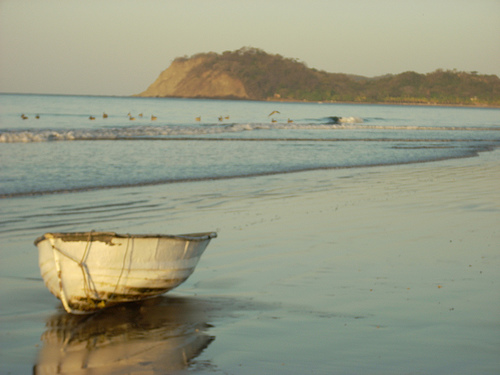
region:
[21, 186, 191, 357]
Boat on the shore.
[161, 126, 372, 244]
Water touching the shore.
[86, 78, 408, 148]
Birds in the water.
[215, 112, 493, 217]
Water in the background.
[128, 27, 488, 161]
Hills behind the water.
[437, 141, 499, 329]
Sand on the shore.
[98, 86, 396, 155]
Rocks in the water.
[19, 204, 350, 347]
White boat on the shore.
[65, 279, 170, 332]
Dirt on the boat.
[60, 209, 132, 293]
Ropes on the boat.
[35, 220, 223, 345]
white boat on wet sand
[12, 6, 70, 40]
white clouds against blue sky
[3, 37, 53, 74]
white clouds against blue sky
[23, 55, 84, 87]
white clouds against blue sky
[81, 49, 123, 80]
white clouds against blue sky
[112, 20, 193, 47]
white clouds against blue sky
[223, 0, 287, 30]
white clouds against blue sky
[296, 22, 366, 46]
white clouds against blue sky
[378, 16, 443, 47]
white clouds against blue sky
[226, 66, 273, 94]
brown mountain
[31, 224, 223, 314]
The boat is old.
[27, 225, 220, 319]
The boat is white.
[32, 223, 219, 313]
The boat is on it's keel.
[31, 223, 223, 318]
The boat is on the beach.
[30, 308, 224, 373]
The boat is reflected in the water.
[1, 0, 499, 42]
The sky is gray and cloudy.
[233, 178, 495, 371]
The beach is wet.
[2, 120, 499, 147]
A wave is coming towards the beach.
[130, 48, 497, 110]
The coast has green in it.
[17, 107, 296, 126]
Birds are moving in the water.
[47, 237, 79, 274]
a white boat on the shore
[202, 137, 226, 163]
the blue ocean in the background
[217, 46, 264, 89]
the mountains in the background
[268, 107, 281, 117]
a white seagull flying by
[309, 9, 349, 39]
the clear blue sky in the background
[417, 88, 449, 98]
the lush green trees in the distance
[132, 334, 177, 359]
the shadow of the boat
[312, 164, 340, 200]
ripples on the shore line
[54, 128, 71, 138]
the waves crashing on the shore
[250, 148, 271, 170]
the blue clear ocean waves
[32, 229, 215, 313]
White boat on shore.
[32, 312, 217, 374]
Shadow of a white boat on the shore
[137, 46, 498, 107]
Large land mass in the distance.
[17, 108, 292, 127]
Many birds over the water.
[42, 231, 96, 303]
Rope on the side of the boat in the shape of a Y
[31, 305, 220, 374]
White boat reflection on the sand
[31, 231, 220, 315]
White boat on the wet sand.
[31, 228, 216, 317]
A white boat washed ashore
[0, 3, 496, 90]
Gray hazy sky.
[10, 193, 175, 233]
Ripples in the shallow water behind the boat.